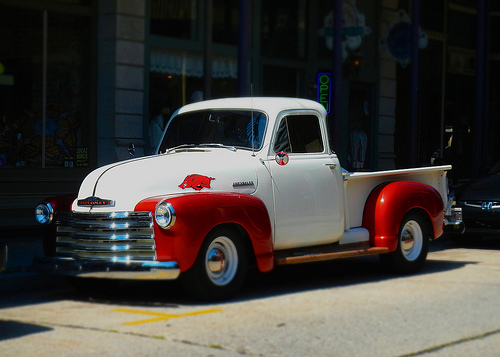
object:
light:
[154, 200, 177, 230]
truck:
[32, 95, 454, 302]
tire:
[178, 221, 259, 301]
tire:
[377, 207, 434, 275]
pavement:
[0, 233, 500, 357]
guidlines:
[118, 308, 227, 328]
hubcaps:
[205, 243, 229, 280]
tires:
[66, 275, 134, 296]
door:
[266, 109, 347, 252]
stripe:
[91, 151, 178, 197]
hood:
[68, 151, 259, 213]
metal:
[362, 180, 445, 252]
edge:
[337, 164, 454, 181]